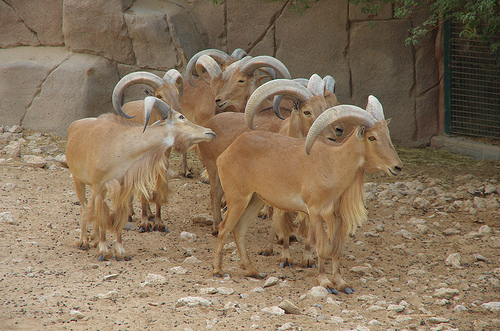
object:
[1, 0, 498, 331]
animal enclosure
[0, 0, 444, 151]
wall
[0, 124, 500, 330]
ground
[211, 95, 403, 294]
goat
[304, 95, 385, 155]
horns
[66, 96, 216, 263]
goat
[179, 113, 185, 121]
eye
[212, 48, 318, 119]
goat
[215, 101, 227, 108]
mouth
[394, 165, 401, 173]
nose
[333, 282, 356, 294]
foot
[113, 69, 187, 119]
horns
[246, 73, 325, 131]
horns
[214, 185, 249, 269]
leg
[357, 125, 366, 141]
ear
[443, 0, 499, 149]
fence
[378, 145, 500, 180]
hay